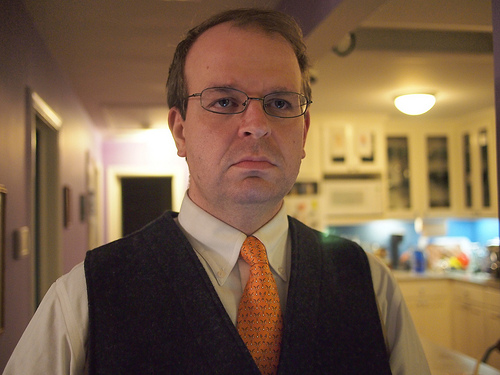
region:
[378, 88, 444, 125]
A white light on the roof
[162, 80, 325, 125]
A pair of glasses on a mans face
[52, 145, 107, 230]
A group of pictures on the wall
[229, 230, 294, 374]
An orange tie with designs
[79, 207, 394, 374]
A dark vest worn by a man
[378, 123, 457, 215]
Two glass cabinets in the kitchen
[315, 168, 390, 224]
A white built in microwave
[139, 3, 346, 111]
A man losing his hair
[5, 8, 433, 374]
A man wearing a vest and white undershirt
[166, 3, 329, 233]
A man with a scowl on his face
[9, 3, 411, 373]
this is a man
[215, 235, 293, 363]
this is a tie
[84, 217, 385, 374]
this is a half sweater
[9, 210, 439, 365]
the shirt is cream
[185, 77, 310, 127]
these are glasses on the man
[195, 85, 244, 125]
this is an eye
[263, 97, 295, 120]
this is an eye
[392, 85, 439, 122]
this is a bulb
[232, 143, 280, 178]
this is a mouth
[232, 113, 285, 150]
this is a nose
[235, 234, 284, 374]
Orange necktie with pattern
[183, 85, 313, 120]
Metal rimmed eyeglasses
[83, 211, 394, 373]
Man's black vest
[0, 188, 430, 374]
Man's white oxford shirt with button down collar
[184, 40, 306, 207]
Man's face with a very serious expression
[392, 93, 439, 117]
Flush mount light illuminating a kitchen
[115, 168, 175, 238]
Doorway to a room that is pitch dark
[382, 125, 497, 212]
Kitchen cabinets with glass fronts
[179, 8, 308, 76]
Receding hairline of a man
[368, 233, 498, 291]
Kitchen countertop with numerous items on it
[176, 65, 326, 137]
man wearing reading glasses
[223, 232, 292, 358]
man wearing a yellow tie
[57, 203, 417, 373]
man wearing a gray vest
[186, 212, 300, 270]
man wearing a white dress shirt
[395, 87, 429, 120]
light on the ceiling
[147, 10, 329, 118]
man with blonde hair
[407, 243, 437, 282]
bottle on the counter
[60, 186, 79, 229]
picture on the wall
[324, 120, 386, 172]
cabinet on the wall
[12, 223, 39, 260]
control switch on the wall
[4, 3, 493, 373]
guy near the kitchen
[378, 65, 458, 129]
light on the ceiling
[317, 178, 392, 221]
white microwave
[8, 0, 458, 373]
guy with short hair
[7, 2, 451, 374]
guy wearing glasses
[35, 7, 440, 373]
guy with a fresh shaved face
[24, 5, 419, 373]
guy wearing a orange tie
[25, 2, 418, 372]
guy wearing a white collard shirt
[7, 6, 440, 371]
guy wearing a black vest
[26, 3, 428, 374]
guy with a side part